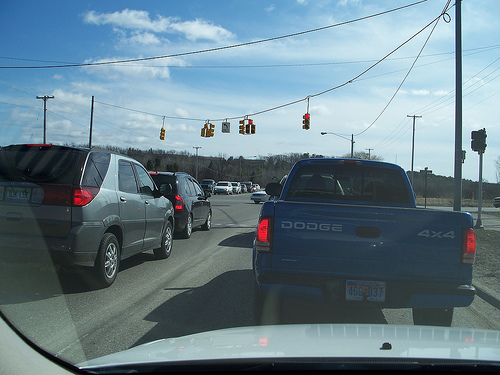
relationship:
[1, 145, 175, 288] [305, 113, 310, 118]
car at light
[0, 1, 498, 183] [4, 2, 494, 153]
cloud in sky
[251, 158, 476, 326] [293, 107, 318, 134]
car sits at light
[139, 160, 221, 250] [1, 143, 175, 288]
black van in front of car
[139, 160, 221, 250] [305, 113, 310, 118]
black van at light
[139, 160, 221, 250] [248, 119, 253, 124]
black van at lights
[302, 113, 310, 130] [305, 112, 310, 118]
stop light with light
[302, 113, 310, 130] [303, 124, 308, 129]
stop light with light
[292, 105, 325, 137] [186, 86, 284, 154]
stop light with lights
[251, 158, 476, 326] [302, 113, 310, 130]
car at stop light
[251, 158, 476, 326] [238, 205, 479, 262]
car has brake lights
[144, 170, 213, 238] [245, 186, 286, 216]
black van making a left turn